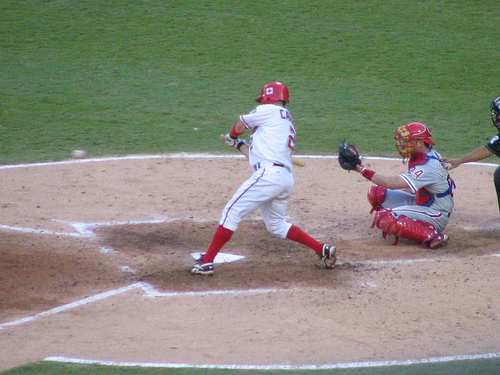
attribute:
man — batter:
[187, 73, 344, 278]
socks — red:
[193, 223, 324, 263]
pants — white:
[215, 167, 292, 240]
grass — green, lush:
[3, 3, 493, 167]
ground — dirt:
[3, 168, 486, 350]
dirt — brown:
[11, 168, 490, 355]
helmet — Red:
[397, 116, 439, 144]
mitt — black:
[330, 136, 360, 169]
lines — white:
[149, 265, 373, 307]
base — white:
[191, 242, 244, 275]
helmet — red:
[257, 79, 293, 100]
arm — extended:
[333, 151, 419, 196]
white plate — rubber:
[186, 242, 251, 271]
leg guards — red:
[362, 186, 445, 249]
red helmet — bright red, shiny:
[253, 81, 290, 103]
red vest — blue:
[400, 154, 439, 207]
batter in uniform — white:
[191, 77, 341, 277]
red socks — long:
[204, 224, 319, 256]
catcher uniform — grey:
[329, 114, 470, 255]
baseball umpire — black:
[454, 82, 499, 197]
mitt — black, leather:
[335, 132, 362, 175]